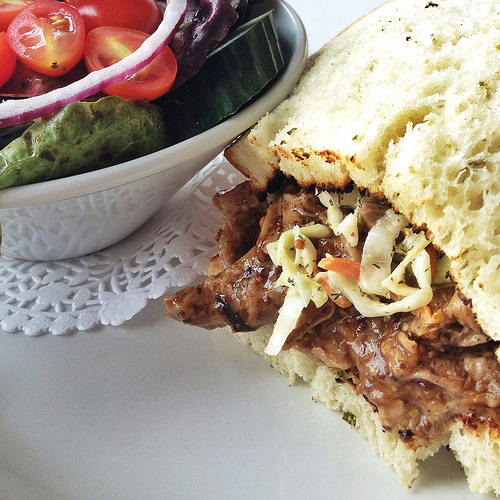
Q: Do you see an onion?
A: Yes, there is an onion.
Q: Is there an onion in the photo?
A: Yes, there is an onion.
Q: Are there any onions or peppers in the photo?
A: Yes, there is an onion.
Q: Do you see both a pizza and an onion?
A: No, there is an onion but no pizzas.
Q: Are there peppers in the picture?
A: No, there are no peppers.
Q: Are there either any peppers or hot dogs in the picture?
A: No, there are no peppers or hot dogs.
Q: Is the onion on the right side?
A: No, the onion is on the left of the image.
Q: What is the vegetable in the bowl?
A: The vegetable is an onion.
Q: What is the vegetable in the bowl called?
A: The vegetable is an onion.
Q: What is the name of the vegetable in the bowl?
A: The vegetable is an onion.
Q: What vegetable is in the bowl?
A: The vegetable is an onion.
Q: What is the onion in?
A: The onion is in the bowl.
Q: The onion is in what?
A: The onion is in the bowl.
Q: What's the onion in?
A: The onion is in the bowl.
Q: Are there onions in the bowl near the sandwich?
A: Yes, there is an onion in the bowl.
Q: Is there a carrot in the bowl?
A: No, there is an onion in the bowl.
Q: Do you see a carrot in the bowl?
A: No, there is an onion in the bowl.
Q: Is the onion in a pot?
A: No, the onion is in a bowl.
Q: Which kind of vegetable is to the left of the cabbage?
A: The vegetable is an onion.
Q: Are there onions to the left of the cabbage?
A: Yes, there is an onion to the left of the cabbage.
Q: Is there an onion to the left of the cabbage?
A: Yes, there is an onion to the left of the cabbage.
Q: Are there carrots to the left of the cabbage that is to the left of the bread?
A: No, there is an onion to the left of the cabbage.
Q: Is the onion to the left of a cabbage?
A: Yes, the onion is to the left of a cabbage.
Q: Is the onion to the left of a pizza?
A: No, the onion is to the left of a cabbage.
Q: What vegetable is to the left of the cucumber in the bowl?
A: The vegetable is an onion.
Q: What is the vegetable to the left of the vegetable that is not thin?
A: The vegetable is an onion.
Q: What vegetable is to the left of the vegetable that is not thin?
A: The vegetable is an onion.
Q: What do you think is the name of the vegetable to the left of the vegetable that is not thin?
A: The vegetable is an onion.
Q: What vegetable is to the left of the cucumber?
A: The vegetable is an onion.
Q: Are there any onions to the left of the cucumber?
A: Yes, there is an onion to the left of the cucumber.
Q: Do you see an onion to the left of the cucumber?
A: Yes, there is an onion to the left of the cucumber.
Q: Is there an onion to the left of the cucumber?
A: Yes, there is an onion to the left of the cucumber.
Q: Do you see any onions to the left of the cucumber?
A: Yes, there is an onion to the left of the cucumber.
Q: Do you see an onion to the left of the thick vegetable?
A: Yes, there is an onion to the left of the cucumber.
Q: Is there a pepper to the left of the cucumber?
A: No, there is an onion to the left of the cucumber.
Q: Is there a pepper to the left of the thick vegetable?
A: No, there is an onion to the left of the cucumber.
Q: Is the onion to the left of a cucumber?
A: Yes, the onion is to the left of a cucumber.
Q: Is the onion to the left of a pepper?
A: No, the onion is to the left of a cucumber.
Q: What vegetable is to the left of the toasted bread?
A: The vegetable is an onion.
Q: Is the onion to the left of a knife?
A: No, the onion is to the left of the bread.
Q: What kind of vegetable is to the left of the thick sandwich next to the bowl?
A: The vegetable is an onion.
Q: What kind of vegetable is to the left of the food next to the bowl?
A: The vegetable is an onion.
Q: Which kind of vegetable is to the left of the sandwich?
A: The vegetable is an onion.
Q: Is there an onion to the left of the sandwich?
A: Yes, there is an onion to the left of the sandwich.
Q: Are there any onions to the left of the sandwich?
A: Yes, there is an onion to the left of the sandwich.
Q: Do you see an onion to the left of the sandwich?
A: Yes, there is an onion to the left of the sandwich.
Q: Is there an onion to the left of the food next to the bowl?
A: Yes, there is an onion to the left of the sandwich.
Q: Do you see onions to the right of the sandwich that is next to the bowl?
A: No, the onion is to the left of the sandwich.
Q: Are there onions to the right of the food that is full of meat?
A: No, the onion is to the left of the sandwich.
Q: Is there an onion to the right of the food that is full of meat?
A: No, the onion is to the left of the sandwich.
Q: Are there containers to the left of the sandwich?
A: No, there is an onion to the left of the sandwich.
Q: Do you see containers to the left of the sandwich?
A: No, there is an onion to the left of the sandwich.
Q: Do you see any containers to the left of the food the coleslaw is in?
A: No, there is an onion to the left of the sandwich.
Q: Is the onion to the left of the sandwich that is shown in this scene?
A: Yes, the onion is to the left of the sandwich.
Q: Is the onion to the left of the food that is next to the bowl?
A: Yes, the onion is to the left of the sandwich.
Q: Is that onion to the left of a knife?
A: No, the onion is to the left of the sandwich.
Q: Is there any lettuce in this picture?
A: Yes, there is lettuce.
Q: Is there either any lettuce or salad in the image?
A: Yes, there is lettuce.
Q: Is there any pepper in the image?
A: No, there are no peppers.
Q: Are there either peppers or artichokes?
A: No, there are no peppers or artichokes.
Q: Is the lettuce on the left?
A: Yes, the lettuce is on the left of the image.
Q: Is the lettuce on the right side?
A: No, the lettuce is on the left of the image.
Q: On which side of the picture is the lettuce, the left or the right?
A: The lettuce is on the left of the image.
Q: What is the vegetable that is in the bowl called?
A: The vegetable is lettuce.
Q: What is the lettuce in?
A: The lettuce is in the bowl.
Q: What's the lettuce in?
A: The lettuce is in the bowl.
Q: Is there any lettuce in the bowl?
A: Yes, there is lettuce in the bowl.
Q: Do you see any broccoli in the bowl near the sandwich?
A: No, there is lettuce in the bowl.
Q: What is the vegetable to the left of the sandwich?
A: The vegetable is lettuce.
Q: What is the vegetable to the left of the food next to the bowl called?
A: The vegetable is lettuce.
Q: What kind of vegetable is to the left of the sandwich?
A: The vegetable is lettuce.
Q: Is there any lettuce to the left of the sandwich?
A: Yes, there is lettuce to the left of the sandwich.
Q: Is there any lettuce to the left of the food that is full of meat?
A: Yes, there is lettuce to the left of the sandwich.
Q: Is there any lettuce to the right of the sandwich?
A: No, the lettuce is to the left of the sandwich.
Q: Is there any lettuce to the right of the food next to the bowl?
A: No, the lettuce is to the left of the sandwich.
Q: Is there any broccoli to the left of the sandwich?
A: No, there is lettuce to the left of the sandwich.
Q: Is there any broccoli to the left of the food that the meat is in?
A: No, there is lettuce to the left of the sandwich.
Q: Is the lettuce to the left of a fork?
A: No, the lettuce is to the left of a sandwich.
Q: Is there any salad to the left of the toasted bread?
A: No, there is lettuce to the left of the bread.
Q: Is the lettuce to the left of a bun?
A: No, the lettuce is to the left of the bread.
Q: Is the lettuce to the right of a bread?
A: No, the lettuce is to the left of a bread.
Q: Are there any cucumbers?
A: Yes, there is a cucumber.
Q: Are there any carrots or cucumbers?
A: Yes, there is a cucumber.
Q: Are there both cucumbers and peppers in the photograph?
A: No, there is a cucumber but no peppers.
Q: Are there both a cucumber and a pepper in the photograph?
A: No, there is a cucumber but no peppers.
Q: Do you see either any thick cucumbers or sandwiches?
A: Yes, there is a thick cucumber.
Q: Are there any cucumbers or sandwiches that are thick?
A: Yes, the cucumber is thick.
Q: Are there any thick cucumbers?
A: Yes, there is a thick cucumber.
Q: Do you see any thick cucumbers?
A: Yes, there is a thick cucumber.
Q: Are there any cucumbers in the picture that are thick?
A: Yes, there is a cucumber that is thick.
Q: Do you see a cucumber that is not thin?
A: Yes, there is a thick cucumber.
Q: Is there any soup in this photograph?
A: No, there is no soup.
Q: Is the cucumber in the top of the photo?
A: Yes, the cucumber is in the top of the image.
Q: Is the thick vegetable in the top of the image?
A: Yes, the cucumber is in the top of the image.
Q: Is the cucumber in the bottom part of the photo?
A: No, the cucumber is in the top of the image.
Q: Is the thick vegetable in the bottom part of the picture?
A: No, the cucumber is in the top of the image.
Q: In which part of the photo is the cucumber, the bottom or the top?
A: The cucumber is in the top of the image.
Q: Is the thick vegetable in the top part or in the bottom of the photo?
A: The cucumber is in the top of the image.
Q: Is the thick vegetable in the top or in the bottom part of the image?
A: The cucumber is in the top of the image.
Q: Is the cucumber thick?
A: Yes, the cucumber is thick.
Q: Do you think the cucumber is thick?
A: Yes, the cucumber is thick.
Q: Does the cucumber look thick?
A: Yes, the cucumber is thick.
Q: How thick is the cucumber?
A: The cucumber is thick.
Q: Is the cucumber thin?
A: No, the cucumber is thick.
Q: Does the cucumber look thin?
A: No, the cucumber is thick.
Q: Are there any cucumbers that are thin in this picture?
A: No, there is a cucumber but it is thick.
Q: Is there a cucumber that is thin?
A: No, there is a cucumber but it is thick.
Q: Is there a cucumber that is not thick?
A: No, there is a cucumber but it is thick.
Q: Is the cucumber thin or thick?
A: The cucumber is thick.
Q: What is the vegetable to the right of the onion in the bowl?
A: The vegetable is a cucumber.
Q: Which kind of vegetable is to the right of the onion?
A: The vegetable is a cucumber.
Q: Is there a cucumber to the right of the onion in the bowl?
A: Yes, there is a cucumber to the right of the onion.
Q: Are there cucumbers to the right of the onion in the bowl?
A: Yes, there is a cucumber to the right of the onion.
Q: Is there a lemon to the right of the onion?
A: No, there is a cucumber to the right of the onion.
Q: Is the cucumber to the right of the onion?
A: Yes, the cucumber is to the right of the onion.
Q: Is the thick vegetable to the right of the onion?
A: Yes, the cucumber is to the right of the onion.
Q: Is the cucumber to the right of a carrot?
A: No, the cucumber is to the right of the onion.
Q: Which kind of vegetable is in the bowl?
A: The vegetable is a cucumber.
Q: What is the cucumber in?
A: The cucumber is in the bowl.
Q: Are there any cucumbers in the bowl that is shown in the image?
A: Yes, there is a cucumber in the bowl.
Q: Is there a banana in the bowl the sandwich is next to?
A: No, there is a cucumber in the bowl.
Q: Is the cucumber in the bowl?
A: Yes, the cucumber is in the bowl.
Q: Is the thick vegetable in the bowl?
A: Yes, the cucumber is in the bowl.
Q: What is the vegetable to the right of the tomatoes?
A: The vegetable is a cucumber.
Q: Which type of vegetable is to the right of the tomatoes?
A: The vegetable is a cucumber.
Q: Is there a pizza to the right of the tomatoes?
A: No, there is a cucumber to the right of the tomatoes.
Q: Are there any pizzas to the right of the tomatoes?
A: No, there is a cucumber to the right of the tomatoes.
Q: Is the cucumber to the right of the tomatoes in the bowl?
A: Yes, the cucumber is to the right of the tomatoes.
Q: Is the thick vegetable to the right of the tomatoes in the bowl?
A: Yes, the cucumber is to the right of the tomatoes.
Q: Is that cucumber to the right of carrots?
A: No, the cucumber is to the right of the tomatoes.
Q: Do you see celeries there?
A: No, there are no celeries.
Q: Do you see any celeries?
A: No, there are no celeries.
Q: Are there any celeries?
A: No, there are no celeries.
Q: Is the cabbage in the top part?
A: Yes, the cabbage is in the top of the image.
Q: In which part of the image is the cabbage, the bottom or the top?
A: The cabbage is in the top of the image.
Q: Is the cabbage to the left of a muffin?
A: No, the cabbage is to the left of the bread.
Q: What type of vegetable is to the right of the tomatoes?
A: The vegetable is a cabbage.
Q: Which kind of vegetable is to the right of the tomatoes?
A: The vegetable is a cabbage.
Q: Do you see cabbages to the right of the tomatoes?
A: Yes, there is a cabbage to the right of the tomatoes.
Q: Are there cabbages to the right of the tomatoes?
A: Yes, there is a cabbage to the right of the tomatoes.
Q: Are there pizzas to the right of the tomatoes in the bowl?
A: No, there is a cabbage to the right of the tomatoes.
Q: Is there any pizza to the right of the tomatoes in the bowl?
A: No, there is a cabbage to the right of the tomatoes.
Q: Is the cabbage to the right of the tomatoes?
A: Yes, the cabbage is to the right of the tomatoes.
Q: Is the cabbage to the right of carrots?
A: No, the cabbage is to the right of the tomatoes.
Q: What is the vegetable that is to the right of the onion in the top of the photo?
A: The vegetable is a cabbage.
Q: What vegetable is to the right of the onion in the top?
A: The vegetable is a cabbage.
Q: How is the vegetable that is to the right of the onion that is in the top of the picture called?
A: The vegetable is a cabbage.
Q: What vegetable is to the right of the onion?
A: The vegetable is a cabbage.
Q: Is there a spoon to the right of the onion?
A: No, there is a cabbage to the right of the onion.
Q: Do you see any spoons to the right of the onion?
A: No, there is a cabbage to the right of the onion.